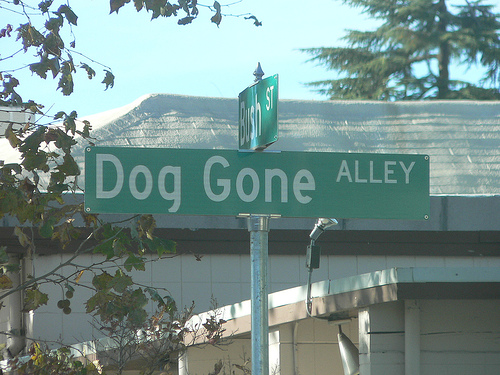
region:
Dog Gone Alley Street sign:
[84, 143, 439, 223]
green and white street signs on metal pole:
[76, 65, 436, 372]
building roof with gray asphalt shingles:
[20, 86, 498, 195]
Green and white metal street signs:
[85, 72, 439, 226]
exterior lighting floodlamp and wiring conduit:
[302, 215, 359, 322]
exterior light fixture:
[335, 324, 360, 374]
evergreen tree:
[301, 0, 448, 94]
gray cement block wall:
[0, 255, 448, 346]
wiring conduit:
[362, 319, 404, 335]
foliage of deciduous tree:
[0, 100, 224, 372]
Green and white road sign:
[70, 140, 454, 247]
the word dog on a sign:
[85, 142, 193, 227]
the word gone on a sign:
[198, 147, 325, 227]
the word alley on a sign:
[332, 155, 424, 191]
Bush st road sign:
[224, 73, 291, 152]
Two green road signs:
[71, 57, 456, 258]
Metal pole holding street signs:
[231, 206, 291, 373]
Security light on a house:
[302, 217, 339, 317]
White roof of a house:
[436, 120, 481, 167]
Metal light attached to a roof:
[315, 314, 356, 373]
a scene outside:
[2, 0, 499, 373]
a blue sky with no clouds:
[1, 2, 498, 144]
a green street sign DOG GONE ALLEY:
[78, 139, 435, 229]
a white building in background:
[0, 80, 497, 373]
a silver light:
[298, 195, 383, 373]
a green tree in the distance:
[286, 0, 498, 111]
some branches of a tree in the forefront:
[0, 0, 272, 371]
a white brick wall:
[20, 250, 499, 368]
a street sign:
[81, 55, 433, 373]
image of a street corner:
[5, 3, 498, 373]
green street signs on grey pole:
[74, 61, 434, 373]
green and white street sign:
[86, 141, 435, 374]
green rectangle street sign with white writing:
[87, 143, 434, 370]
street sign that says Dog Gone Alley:
[82, 135, 432, 374]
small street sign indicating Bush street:
[233, 60, 285, 153]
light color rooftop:
[0, 72, 497, 254]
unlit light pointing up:
[304, 216, 341, 242]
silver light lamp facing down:
[335, 326, 360, 373]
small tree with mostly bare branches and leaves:
[5, 292, 229, 374]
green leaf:
[99, 65, 116, 91]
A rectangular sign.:
[83, 146, 430, 213]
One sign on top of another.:
[80, 74, 432, 222]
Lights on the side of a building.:
[302, 206, 362, 373]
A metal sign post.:
[240, 211, 280, 373]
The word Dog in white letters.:
[91, 149, 184, 213]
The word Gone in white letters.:
[200, 152, 319, 209]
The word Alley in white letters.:
[335, 157, 417, 187]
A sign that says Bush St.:
[235, 72, 281, 150]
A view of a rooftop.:
[0, 92, 499, 196]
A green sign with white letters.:
[85, 145, 429, 221]